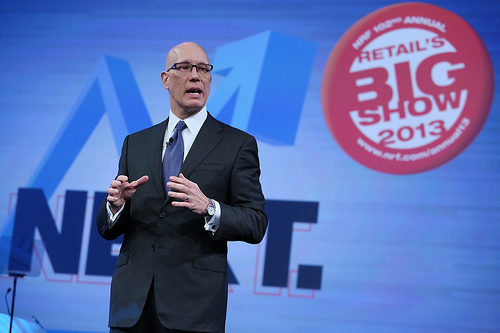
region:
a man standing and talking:
[93, 37, 271, 331]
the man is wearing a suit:
[92, 115, 269, 330]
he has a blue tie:
[161, 116, 193, 198]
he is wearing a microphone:
[163, 132, 178, 151]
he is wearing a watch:
[206, 199, 216, 224]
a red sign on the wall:
[318, 2, 495, 172]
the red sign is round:
[317, 2, 496, 177]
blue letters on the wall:
[7, 37, 342, 315]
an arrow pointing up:
[200, 27, 311, 146]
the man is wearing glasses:
[164, 59, 212, 75]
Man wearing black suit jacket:
[95, 41, 267, 331]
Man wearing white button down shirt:
[97, 38, 267, 331]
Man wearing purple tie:
[92, 40, 268, 330]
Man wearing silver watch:
[80, 35, 267, 330]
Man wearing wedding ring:
[90, 40, 265, 327]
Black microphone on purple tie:
[160, 135, 175, 145]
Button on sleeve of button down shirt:
[209, 220, 220, 231]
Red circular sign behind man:
[320, 1, 493, 173]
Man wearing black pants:
[97, 41, 272, 331]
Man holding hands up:
[92, 40, 272, 330]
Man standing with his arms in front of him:
[94, 34, 259, 329]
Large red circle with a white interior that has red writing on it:
[298, 3, 494, 195]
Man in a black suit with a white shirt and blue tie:
[73, 36, 278, 331]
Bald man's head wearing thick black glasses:
[157, 37, 221, 113]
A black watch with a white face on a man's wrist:
[190, 185, 229, 239]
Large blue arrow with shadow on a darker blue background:
[209, 25, 328, 147]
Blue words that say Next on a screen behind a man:
[0, 175, 345, 300]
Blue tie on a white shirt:
[155, 117, 195, 186]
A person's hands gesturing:
[105, 171, 214, 227]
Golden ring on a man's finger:
[183, 185, 193, 207]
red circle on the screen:
[320, 4, 495, 176]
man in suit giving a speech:
[97, 42, 266, 329]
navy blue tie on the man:
[158, 119, 184, 192]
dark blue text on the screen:
[10, 186, 322, 304]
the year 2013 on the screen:
[377, 116, 447, 143]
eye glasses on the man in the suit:
[165, 56, 215, 74]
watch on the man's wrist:
[202, 195, 214, 222]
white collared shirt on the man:
[162, 111, 207, 184]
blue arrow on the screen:
[30, 29, 313, 197]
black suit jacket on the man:
[100, 116, 265, 331]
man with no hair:
[150, 36, 221, 121]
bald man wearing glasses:
[153, 43, 221, 120]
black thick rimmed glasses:
[161, 54, 217, 79]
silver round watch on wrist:
[192, 188, 230, 225]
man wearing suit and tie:
[92, 33, 291, 331]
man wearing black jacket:
[100, 34, 287, 330]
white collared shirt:
[161, 98, 215, 195]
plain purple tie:
[152, 109, 192, 212]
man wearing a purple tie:
[97, 35, 276, 330]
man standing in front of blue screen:
[109, 45, 262, 327]